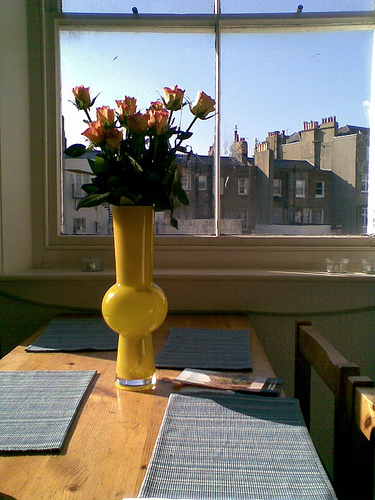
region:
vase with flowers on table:
[53, 81, 216, 386]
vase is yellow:
[98, 204, 167, 389]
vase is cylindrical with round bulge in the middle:
[97, 206, 169, 386]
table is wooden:
[2, 312, 312, 499]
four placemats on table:
[5, 317, 329, 499]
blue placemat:
[143, 390, 334, 497]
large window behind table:
[27, 5, 374, 266]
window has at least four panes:
[35, 0, 372, 240]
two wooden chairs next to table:
[280, 317, 373, 498]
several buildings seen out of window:
[63, 101, 366, 235]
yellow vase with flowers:
[62, 66, 232, 391]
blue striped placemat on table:
[133, 381, 334, 498]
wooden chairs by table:
[272, 309, 373, 498]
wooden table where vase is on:
[80, 397, 139, 497]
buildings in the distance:
[221, 109, 373, 224]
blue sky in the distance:
[231, 40, 363, 103]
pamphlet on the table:
[172, 359, 288, 402]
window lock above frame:
[122, 1, 148, 25]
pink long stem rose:
[65, 83, 102, 111]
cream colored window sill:
[175, 259, 374, 317]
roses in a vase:
[60, 73, 213, 251]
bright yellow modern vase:
[74, 180, 175, 400]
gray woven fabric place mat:
[141, 384, 327, 497]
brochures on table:
[160, 360, 291, 403]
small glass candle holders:
[305, 252, 373, 280]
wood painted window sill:
[5, 232, 373, 316]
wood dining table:
[7, 310, 310, 499]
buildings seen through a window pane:
[210, 8, 374, 248]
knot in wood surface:
[39, 458, 98, 498]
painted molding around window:
[18, 114, 99, 268]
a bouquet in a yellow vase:
[62, 81, 218, 390]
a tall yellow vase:
[101, 205, 168, 391]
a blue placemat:
[137, 391, 337, 499]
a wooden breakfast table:
[0, 310, 338, 498]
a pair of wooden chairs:
[294, 318, 373, 499]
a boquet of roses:
[67, 83, 218, 231]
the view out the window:
[25, 0, 373, 271]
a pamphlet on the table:
[173, 366, 286, 394]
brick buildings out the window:
[63, 115, 372, 235]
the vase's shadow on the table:
[135, 378, 307, 426]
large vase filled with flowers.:
[57, 70, 192, 401]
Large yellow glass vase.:
[84, 189, 175, 400]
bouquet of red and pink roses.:
[53, 62, 221, 211]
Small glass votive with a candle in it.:
[71, 251, 109, 277]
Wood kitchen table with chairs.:
[4, 294, 351, 498]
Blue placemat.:
[134, 385, 346, 497]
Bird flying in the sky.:
[105, 46, 124, 65]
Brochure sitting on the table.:
[167, 358, 302, 403]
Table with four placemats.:
[3, 291, 350, 498]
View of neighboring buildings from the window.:
[54, 15, 374, 243]